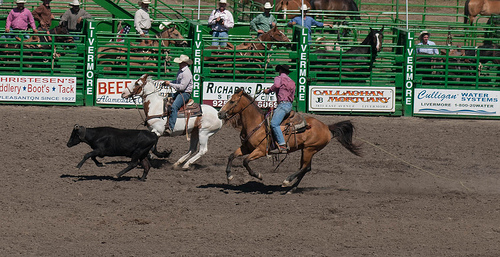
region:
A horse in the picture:
[216, 84, 367, 203]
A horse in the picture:
[118, 71, 226, 177]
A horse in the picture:
[0, 18, 75, 85]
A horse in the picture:
[93, 22, 190, 82]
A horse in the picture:
[191, 21, 293, 76]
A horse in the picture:
[306, 24, 388, 86]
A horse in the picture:
[406, 34, 499, 86]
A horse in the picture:
[458, 0, 499, 30]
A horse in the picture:
[308, 0, 365, 29]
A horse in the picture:
[270, 0, 312, 22]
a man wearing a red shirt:
[258, 50, 307, 112]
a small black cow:
[55, 116, 174, 185]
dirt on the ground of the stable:
[182, 205, 254, 245]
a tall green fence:
[301, 24, 417, 116]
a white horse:
[122, 68, 227, 187]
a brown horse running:
[206, 84, 362, 206]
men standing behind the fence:
[7, 0, 494, 87]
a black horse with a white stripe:
[304, 19, 392, 82]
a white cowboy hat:
[166, 46, 197, 64]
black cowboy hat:
[272, 55, 300, 78]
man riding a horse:
[231, 33, 349, 195]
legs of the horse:
[201, 148, 316, 242]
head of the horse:
[208, 82, 255, 135]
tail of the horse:
[329, 104, 377, 166]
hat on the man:
[167, 43, 199, 78]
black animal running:
[48, 123, 169, 202]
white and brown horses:
[151, 55, 316, 177]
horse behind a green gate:
[355, 17, 396, 65]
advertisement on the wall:
[306, 77, 395, 118]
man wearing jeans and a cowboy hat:
[163, 48, 204, 118]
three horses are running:
[37, 72, 357, 203]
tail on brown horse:
[334, 120, 373, 157]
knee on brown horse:
[242, 155, 262, 170]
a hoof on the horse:
[249, 170, 266, 185]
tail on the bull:
[152, 138, 167, 160]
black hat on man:
[275, 58, 295, 73]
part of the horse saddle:
[290, 112, 307, 129]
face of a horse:
[366, 23, 386, 54]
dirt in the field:
[52, 176, 144, 235]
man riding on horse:
[136, 42, 218, 139]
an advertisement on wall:
[414, 86, 489, 116]